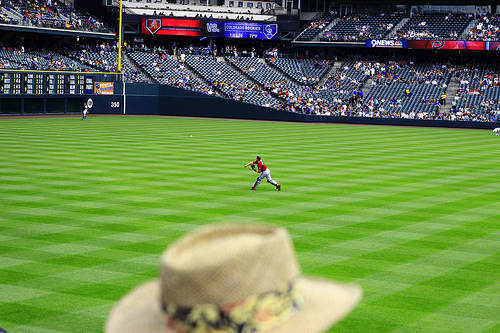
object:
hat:
[104, 219, 361, 332]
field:
[0, 112, 497, 332]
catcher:
[245, 156, 281, 191]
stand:
[0, 0, 500, 132]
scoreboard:
[3, 74, 85, 96]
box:
[212, 38, 291, 57]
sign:
[94, 82, 114, 95]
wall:
[85, 83, 159, 114]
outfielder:
[82, 103, 87, 120]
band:
[159, 281, 299, 331]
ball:
[190, 135, 193, 138]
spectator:
[374, 98, 378, 105]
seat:
[405, 106, 412, 110]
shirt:
[441, 95, 446, 99]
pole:
[118, 0, 122, 70]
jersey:
[253, 160, 268, 172]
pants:
[253, 168, 277, 187]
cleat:
[276, 184, 281, 191]